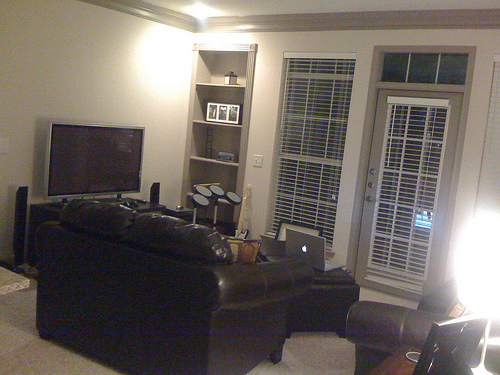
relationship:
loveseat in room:
[32, 200, 315, 374] [2, 1, 500, 374]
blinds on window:
[271, 52, 356, 265] [260, 50, 358, 266]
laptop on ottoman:
[285, 227, 345, 274] [255, 241, 359, 339]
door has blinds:
[344, 44, 478, 302] [368, 97, 454, 296]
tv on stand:
[45, 119, 148, 196] [27, 197, 168, 267]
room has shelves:
[2, 1, 500, 374] [182, 40, 258, 233]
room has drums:
[2, 1, 500, 374] [189, 185, 244, 230]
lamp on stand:
[447, 207, 498, 374] [363, 346, 425, 374]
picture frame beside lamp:
[413, 317, 488, 374] [447, 207, 498, 374]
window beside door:
[260, 50, 358, 266] [344, 44, 478, 302]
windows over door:
[380, 52, 470, 85] [344, 44, 478, 302]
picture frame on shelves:
[206, 102, 242, 126] [182, 40, 258, 233]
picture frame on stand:
[413, 317, 488, 374] [363, 346, 425, 374]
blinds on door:
[368, 97, 454, 296] [344, 44, 478, 302]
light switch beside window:
[250, 153, 267, 171] [260, 50, 358, 266]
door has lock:
[344, 44, 478, 302] [366, 166, 378, 177]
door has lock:
[344, 44, 478, 302] [366, 179, 378, 191]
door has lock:
[344, 44, 478, 302] [364, 194, 375, 207]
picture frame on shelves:
[413, 317, 488, 374] [182, 40, 258, 233]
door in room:
[344, 44, 478, 302] [2, 1, 500, 374]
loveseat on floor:
[32, 200, 315, 374] [0, 276, 396, 375]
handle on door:
[365, 195, 384, 207] [344, 44, 478, 302]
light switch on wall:
[250, 153, 267, 171] [199, 31, 500, 284]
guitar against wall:
[235, 184, 253, 240] [199, 31, 500, 284]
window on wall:
[260, 50, 358, 266] [199, 31, 500, 284]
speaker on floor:
[13, 186, 30, 264] [0, 276, 396, 375]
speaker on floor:
[151, 181, 162, 205] [0, 276, 396, 375]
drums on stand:
[189, 185, 244, 230] [182, 205, 225, 232]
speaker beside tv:
[13, 186, 30, 264] [45, 119, 148, 196]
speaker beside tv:
[151, 181, 162, 205] [45, 119, 148, 196]